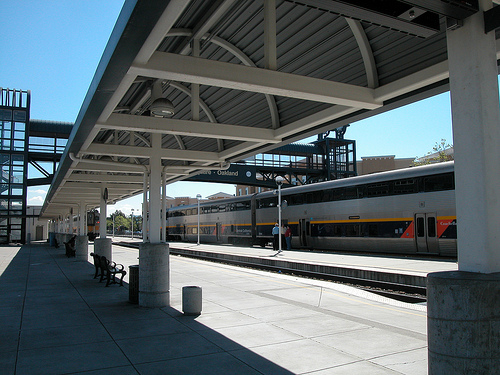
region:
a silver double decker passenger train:
[254, 157, 454, 255]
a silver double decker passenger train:
[163, 191, 255, 247]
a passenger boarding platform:
[105, 229, 457, 292]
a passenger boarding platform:
[0, 235, 478, 373]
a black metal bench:
[88, 250, 123, 287]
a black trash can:
[126, 261, 139, 306]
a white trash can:
[180, 283, 202, 318]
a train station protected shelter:
[35, 0, 492, 374]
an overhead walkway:
[23, 118, 318, 191]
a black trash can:
[60, 238, 74, 258]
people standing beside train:
[271, 219, 293, 252]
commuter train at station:
[167, 163, 453, 245]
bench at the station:
[91, 250, 126, 287]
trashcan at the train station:
[182, 286, 202, 316]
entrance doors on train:
[416, 210, 437, 256]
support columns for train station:
[139, 111, 168, 309]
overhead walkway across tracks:
[0, 108, 355, 176]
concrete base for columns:
[138, 240, 173, 310]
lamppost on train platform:
[276, 176, 283, 255]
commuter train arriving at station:
[71, 208, 104, 237]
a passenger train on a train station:
[175, 160, 457, 267]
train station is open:
[0, 0, 499, 373]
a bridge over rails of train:
[26, 105, 359, 190]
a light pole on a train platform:
[268, 168, 290, 257]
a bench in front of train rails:
[83, 245, 129, 290]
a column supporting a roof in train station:
[416, 0, 499, 373]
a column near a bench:
[93, 180, 116, 253]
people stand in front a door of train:
[263, 215, 293, 252]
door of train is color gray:
[407, 208, 442, 260]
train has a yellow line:
[171, 159, 454, 257]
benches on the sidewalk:
[43, 208, 158, 318]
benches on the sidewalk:
[19, 179, 215, 347]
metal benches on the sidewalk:
[33, 196, 185, 324]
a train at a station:
[154, 147, 444, 301]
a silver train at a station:
[144, 140, 499, 303]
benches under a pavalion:
[34, 68, 321, 372]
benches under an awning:
[4, 47, 469, 372]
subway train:
[140, 160, 460, 265]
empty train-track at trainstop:
[110, 230, 425, 300]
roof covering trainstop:
[35, 15, 490, 210]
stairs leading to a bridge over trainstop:
[0, 110, 25, 240]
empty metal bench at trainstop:
[85, 250, 125, 285]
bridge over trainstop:
[25, 115, 355, 185]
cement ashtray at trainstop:
[175, 280, 205, 315]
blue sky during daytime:
[345, 90, 450, 155]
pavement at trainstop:
[0, 250, 425, 370]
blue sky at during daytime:
[0, 1, 120, 123]